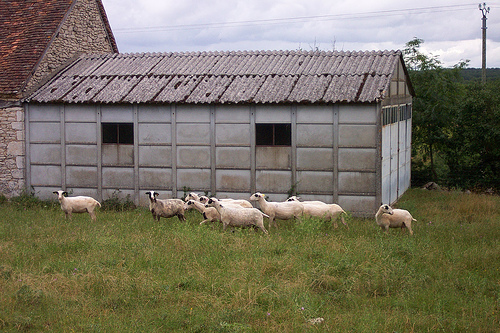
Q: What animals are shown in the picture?
A: Sheep.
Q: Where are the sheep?
A: In the field.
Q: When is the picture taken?
A: Daytime.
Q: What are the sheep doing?
A: Grazing.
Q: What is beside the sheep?
A: Building.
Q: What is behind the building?
A: Trees.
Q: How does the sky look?
A: Cloudy.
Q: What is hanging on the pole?
A: Power cable.